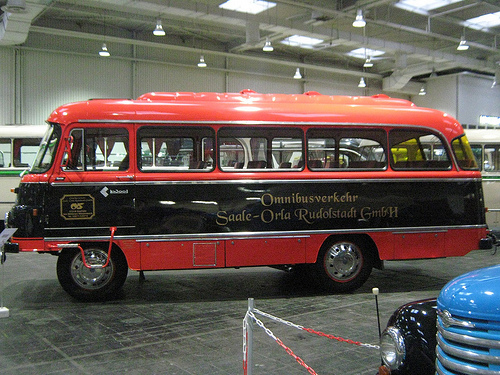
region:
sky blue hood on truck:
[438, 308, 498, 373]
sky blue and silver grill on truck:
[438, 306, 498, 373]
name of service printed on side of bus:
[211, 191, 406, 228]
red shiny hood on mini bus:
[60, 89, 450, 121]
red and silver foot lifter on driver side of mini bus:
[56, 229, 126, 271]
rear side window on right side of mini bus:
[388, 130, 455, 168]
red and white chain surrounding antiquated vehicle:
[261, 311, 378, 372]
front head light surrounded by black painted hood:
[376, 306, 433, 373]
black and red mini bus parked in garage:
[10, 87, 484, 242]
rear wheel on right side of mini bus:
[317, 237, 377, 290]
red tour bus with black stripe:
[6, 85, 499, 296]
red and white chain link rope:
[230, 292, 374, 373]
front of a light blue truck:
[367, 265, 492, 365]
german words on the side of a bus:
[184, 190, 412, 227]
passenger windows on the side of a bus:
[146, 128, 378, 165]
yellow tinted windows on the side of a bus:
[388, 122, 475, 169]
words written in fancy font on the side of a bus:
[180, 187, 419, 229]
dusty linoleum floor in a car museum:
[73, 315, 180, 359]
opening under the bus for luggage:
[141, 232, 313, 272]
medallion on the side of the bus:
[53, 190, 107, 228]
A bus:
[199, 143, 381, 274]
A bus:
[144, 71, 250, 279]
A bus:
[218, 162, 310, 283]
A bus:
[205, 75, 306, 250]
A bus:
[216, 92, 338, 342]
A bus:
[204, 110, 276, 342]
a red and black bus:
[23, 91, 498, 287]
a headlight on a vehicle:
[374, 325, 410, 372]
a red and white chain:
[239, 291, 321, 369]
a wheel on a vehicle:
[314, 234, 370, 289]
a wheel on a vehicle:
[62, 248, 128, 301]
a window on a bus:
[133, 124, 218, 171]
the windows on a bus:
[219, 120, 442, 177]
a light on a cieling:
[144, 9, 181, 56]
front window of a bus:
[30, 108, 62, 173]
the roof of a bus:
[139, 81, 431, 121]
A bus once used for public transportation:
[0, 84, 492, 291]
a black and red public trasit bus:
[6, 88, 496, 290]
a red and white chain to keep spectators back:
[231, 298, 386, 374]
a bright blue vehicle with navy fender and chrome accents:
[369, 266, 499, 373]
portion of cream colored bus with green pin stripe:
[469, 120, 499, 234]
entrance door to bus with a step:
[50, 101, 147, 283]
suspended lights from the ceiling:
[64, 9, 469, 87]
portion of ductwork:
[366, 50, 431, 97]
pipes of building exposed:
[5, 31, 377, 91]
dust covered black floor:
[6, 300, 321, 374]